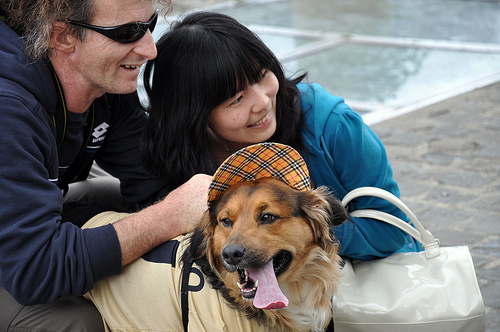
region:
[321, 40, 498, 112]
A window on the floor.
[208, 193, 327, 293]
A Brown and black dog sticking his tongue out.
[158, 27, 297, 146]
An Asian woman whom is smiling.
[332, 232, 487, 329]
A white purse.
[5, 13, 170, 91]
A older man who is wearing black sun glasses.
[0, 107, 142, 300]
A dark blue sweater.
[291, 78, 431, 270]
A woman is wearing a light blue sweater.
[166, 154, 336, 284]
The dog is wearing a checkered cap.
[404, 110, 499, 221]
There is concrete flooring.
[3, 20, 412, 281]
A group picture with a dog man and woman.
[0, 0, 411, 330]
two people posing with a dog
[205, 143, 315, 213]
a plaid hat on the dog's head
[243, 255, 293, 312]
the dog's tongue sticking out of it's mouth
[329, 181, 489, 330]
a shiny white purse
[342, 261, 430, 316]
reflections of light on the surface of the purse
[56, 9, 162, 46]
sunglasses on the man's face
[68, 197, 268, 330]
beige colored clothes on the dog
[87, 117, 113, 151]
a logo on the man's shirt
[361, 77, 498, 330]
a brown cobblestone path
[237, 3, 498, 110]
reflections in the glass surface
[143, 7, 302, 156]
head of a person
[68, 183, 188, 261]
arm of a person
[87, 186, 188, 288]
an arm of a person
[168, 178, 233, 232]
hand of a person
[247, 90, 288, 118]
nose of a person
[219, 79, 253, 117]
eye of a person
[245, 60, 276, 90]
eye of a person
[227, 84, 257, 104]
an eye of a person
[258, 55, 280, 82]
an eye of a person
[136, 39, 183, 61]
nose of a person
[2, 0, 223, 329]
this is a man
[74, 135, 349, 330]
this is a dog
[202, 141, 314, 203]
thats the dog hat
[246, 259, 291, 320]
this is his tongue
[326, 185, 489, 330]
this is a purse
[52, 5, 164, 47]
these are some glasses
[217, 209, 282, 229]
these are his eyes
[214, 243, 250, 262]
this is his nose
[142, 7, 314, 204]
this is her black hair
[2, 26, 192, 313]
thats his blue jacket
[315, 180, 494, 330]
Woman holding a purse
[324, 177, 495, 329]
Woman is holding a purse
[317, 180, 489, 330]
Woman holding a white purse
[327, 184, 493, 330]
Woman is holding a white purse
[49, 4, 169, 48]
Man wearing sunglasses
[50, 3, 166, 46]
Man is wearing sunglasses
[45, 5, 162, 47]
Man wearing black sunglasses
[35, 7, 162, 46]
Man is wearing black sunglasses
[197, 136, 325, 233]
Dog wearing a hat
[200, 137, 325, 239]
Dog is wearing a hat